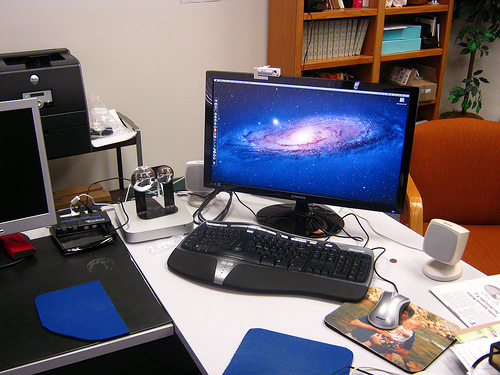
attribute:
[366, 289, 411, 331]
computer mouse — silver, corded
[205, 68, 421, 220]
computer monitor — black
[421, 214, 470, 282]
speaker — small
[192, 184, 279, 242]
cables — computer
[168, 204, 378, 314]
computer keyboard — black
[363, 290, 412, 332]
mouse — silver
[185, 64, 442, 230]
computer — black, monitor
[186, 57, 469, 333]
computer — silver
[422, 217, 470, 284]
computer speaker — single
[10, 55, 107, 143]
printer — black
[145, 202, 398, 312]
keyboard — black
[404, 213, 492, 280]
speaker — small, white, exterior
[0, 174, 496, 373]
tabletop — white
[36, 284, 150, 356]
pad — blue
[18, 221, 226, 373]
desk — black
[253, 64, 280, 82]
webcam — white, small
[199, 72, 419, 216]
monitor — computer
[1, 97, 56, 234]
monitor — computer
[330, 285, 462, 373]
mouse pad — photo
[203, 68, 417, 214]
screen — computer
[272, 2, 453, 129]
bookcase — brown, wooden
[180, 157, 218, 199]
speaker — small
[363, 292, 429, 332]
mouse — silver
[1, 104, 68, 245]
monitor — silver framed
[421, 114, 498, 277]
chair — orange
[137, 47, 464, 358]
computer — black framed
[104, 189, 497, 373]
desk — white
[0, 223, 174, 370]
desk — black